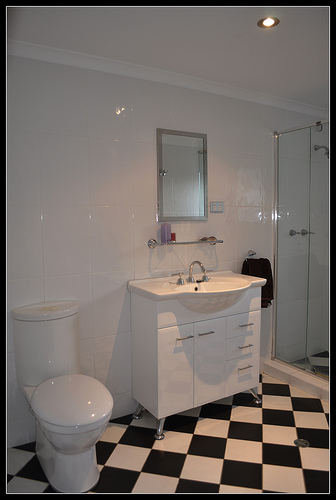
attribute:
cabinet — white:
[158, 310, 260, 394]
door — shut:
[161, 332, 190, 414]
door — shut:
[202, 367, 220, 394]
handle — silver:
[179, 337, 192, 342]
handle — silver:
[202, 333, 208, 337]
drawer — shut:
[230, 319, 261, 333]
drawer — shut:
[231, 342, 256, 356]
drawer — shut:
[232, 363, 257, 388]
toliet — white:
[35, 313, 108, 484]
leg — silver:
[154, 420, 163, 439]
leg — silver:
[251, 391, 261, 403]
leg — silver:
[136, 407, 144, 415]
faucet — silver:
[193, 260, 202, 269]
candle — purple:
[159, 226, 171, 244]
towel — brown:
[254, 262, 270, 274]